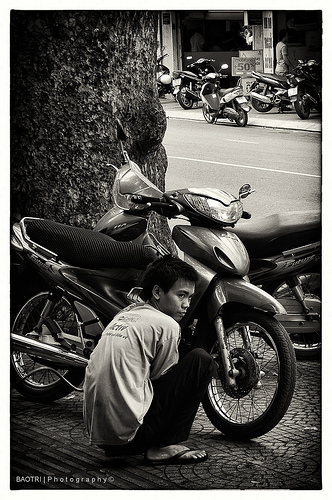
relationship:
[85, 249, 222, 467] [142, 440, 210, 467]
man has flip flops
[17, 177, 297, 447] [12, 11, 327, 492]
motorcycle in scene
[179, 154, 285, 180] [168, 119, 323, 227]
line on road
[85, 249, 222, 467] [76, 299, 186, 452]
man wears shirt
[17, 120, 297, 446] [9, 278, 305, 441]
motorcycle has wheels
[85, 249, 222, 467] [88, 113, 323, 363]
man next bike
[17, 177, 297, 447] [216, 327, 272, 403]
motorcycle has spokes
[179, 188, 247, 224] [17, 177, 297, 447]
front light on motorcycle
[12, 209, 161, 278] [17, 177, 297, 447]
seat on motorcycle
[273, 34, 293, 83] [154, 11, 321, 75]
woman front building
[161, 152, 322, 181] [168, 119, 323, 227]
line on road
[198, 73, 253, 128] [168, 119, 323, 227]
bike parked in road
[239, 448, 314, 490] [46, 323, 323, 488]
bricks of sidewalk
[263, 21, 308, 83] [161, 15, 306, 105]
woman outside of shop